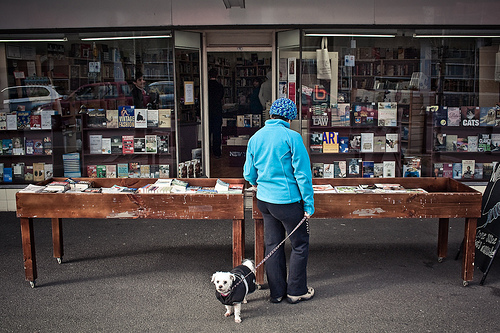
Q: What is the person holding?
A: A dog leash.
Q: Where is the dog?
A: On a leash.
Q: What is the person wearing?
A: A blue jacket.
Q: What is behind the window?
A: Books.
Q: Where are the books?
A: In the window.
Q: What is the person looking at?
A: The books.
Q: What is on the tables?
A: Books.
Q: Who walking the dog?
A: The woman.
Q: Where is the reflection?
A: IN the window.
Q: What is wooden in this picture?
A: The table.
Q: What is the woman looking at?
A: Books.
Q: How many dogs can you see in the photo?
A: 1.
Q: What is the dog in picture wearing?
A: A coat.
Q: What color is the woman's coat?
A: Teal.